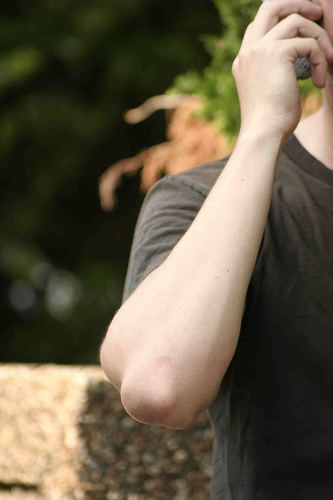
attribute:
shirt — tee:
[136, 117, 330, 499]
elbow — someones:
[94, 311, 237, 445]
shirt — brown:
[112, 133, 332, 305]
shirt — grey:
[131, 164, 332, 386]